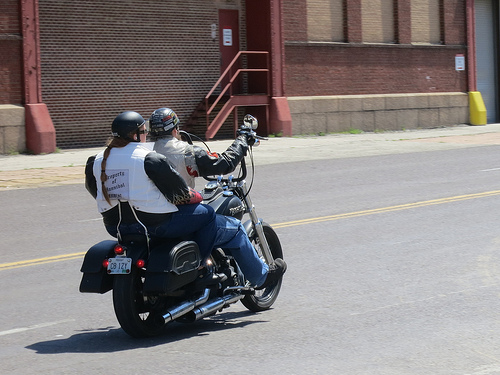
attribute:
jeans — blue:
[100, 200, 220, 267]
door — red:
[218, 11, 248, 88]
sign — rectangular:
[447, 48, 470, 86]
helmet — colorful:
[147, 94, 192, 155]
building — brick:
[3, 0, 490, 147]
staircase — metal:
[180, 45, 282, 136]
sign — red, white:
[454, 53, 466, 73]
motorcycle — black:
[94, 172, 300, 330]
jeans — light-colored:
[216, 212, 268, 290]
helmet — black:
[92, 105, 149, 140]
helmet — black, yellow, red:
[139, 107, 184, 132]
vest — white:
[120, 153, 147, 208]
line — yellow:
[277, 188, 498, 233]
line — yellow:
[3, 248, 81, 274]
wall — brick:
[29, 9, 437, 126]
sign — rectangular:
[449, 50, 471, 75]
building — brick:
[279, 0, 482, 92]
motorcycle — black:
[78, 114, 287, 340]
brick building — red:
[5, 0, 472, 147]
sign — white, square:
[220, 27, 235, 47]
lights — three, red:
[99, 245, 147, 275]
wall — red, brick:
[43, 5, 225, 110]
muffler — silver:
[159, 302, 193, 321]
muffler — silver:
[208, 291, 232, 313]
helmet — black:
[97, 109, 142, 136]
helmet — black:
[107, 122, 140, 147]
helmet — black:
[161, 101, 187, 141]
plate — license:
[99, 253, 139, 282]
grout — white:
[47, 73, 181, 86]